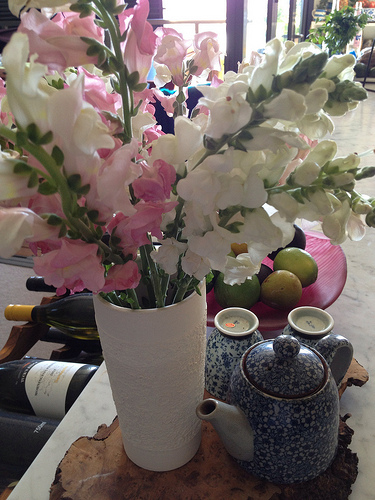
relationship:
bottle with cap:
[1, 291, 105, 349] [1, 300, 35, 323]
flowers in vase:
[0, 0, 372, 308] [93, 273, 206, 470]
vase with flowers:
[93, 273, 206, 470] [0, 0, 372, 308]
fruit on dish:
[208, 220, 318, 308] [205, 227, 348, 331]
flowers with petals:
[29, 140, 176, 307] [128, 172, 167, 202]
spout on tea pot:
[191, 387, 250, 448] [209, 357, 358, 475]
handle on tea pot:
[311, 326, 370, 375] [224, 334, 369, 449]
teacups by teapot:
[205, 308, 374, 367] [221, 347, 344, 438]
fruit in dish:
[211, 255, 317, 284] [215, 229, 365, 319]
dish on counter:
[275, 223, 340, 283] [342, 261, 374, 334]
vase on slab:
[90, 260, 209, 476] [73, 408, 276, 488]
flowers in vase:
[27, 35, 255, 251] [91, 256, 231, 459]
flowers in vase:
[39, 63, 284, 253] [89, 285, 196, 431]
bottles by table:
[0, 347, 110, 399] [41, 373, 122, 494]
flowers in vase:
[31, 49, 198, 252] [93, 278, 235, 458]